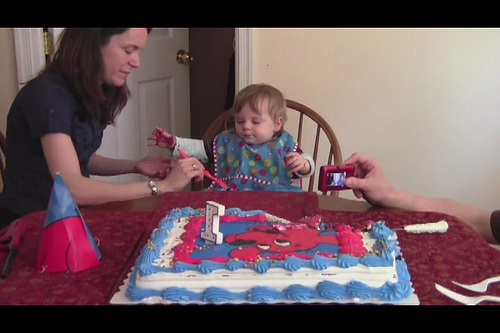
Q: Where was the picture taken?
A: At a party.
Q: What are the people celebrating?
A: A birthday.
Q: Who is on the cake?
A: Clifford.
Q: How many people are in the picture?
A: 3.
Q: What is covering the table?
A: A table cloth.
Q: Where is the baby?
A: In a chair.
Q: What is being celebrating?
A: One year birthday party.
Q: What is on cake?
A: Dog.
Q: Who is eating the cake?
A: The baby.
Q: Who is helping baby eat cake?
A: The mom.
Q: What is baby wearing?
A: A bib.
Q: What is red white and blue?
A: Clifford the dog cake.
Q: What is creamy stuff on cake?
A: Icing.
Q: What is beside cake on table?
A: Birthday hat.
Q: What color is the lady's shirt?
A: Black.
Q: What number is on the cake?
A: 1.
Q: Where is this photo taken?
A: At the table.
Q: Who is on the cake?
A: Clifford.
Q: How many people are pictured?
A: 3.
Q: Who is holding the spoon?
A: The woman.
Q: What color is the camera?
A: Red.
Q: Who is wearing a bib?
A: The baby.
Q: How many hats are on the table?
A: 1.